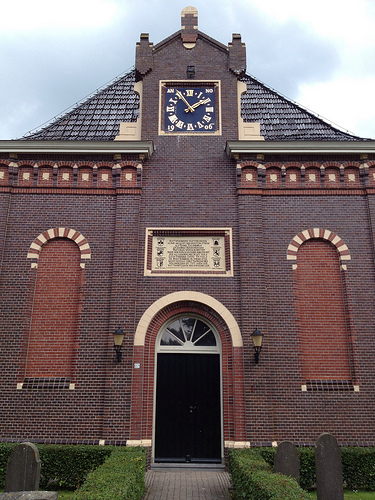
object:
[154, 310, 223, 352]
window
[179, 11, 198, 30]
cross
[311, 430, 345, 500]
tombstone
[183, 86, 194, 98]
12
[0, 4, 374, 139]
roof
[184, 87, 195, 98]
numerals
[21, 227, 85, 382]
window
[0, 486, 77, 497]
cemetary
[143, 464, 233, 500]
sidewalk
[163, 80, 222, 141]
clock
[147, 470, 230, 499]
floor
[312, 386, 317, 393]
brick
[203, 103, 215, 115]
numeral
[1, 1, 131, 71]
sky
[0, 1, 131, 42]
cloud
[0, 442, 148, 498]
bushes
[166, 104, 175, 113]
9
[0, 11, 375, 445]
church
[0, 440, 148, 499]
hedge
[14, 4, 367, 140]
shingled roof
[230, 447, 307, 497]
shurbs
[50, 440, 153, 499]
shurbs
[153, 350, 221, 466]
double doors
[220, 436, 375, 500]
bushes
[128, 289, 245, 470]
arched doorway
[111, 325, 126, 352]
light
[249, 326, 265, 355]
light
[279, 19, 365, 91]
clouds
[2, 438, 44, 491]
tombstone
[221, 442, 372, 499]
hedges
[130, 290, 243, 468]
entrance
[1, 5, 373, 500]
building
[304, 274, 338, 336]
bricks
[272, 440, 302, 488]
tombstone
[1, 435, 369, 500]
yard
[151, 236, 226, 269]
plaque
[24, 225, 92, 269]
top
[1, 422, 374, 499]
cemetary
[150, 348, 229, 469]
door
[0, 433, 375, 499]
hedge row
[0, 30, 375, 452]
wall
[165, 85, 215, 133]
face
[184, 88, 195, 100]
numbers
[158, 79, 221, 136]
time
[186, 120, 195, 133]
number